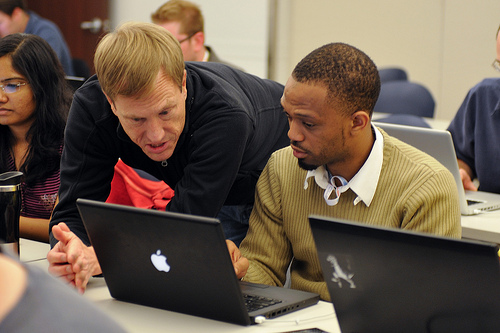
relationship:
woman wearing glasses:
[1, 32, 65, 243] [0, 79, 28, 92]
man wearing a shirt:
[223, 43, 463, 304] [239, 125, 463, 303]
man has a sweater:
[223, 43, 463, 304] [239, 125, 462, 301]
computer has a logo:
[77, 197, 319, 326] [150, 250, 170, 276]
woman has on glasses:
[1, 32, 65, 243] [0, 79, 28, 92]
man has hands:
[223, 43, 463, 304] [226, 239, 248, 280]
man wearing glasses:
[152, 2, 224, 63] [177, 31, 197, 44]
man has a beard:
[223, 43, 463, 304] [299, 158, 316, 170]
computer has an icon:
[77, 197, 322, 326] [150, 249, 169, 274]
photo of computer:
[0, 2, 499, 333] [77, 197, 322, 326]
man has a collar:
[223, 43, 463, 304] [304, 121, 384, 207]